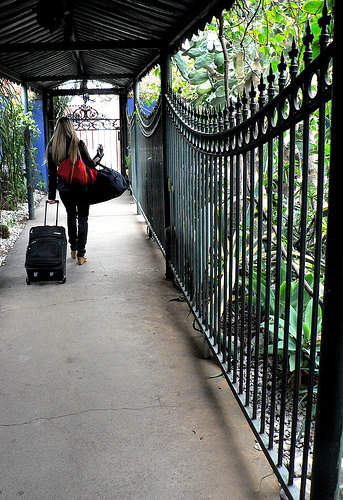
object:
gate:
[48, 115, 122, 172]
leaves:
[256, 43, 262, 55]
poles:
[266, 132, 285, 454]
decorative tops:
[313, 0, 334, 53]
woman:
[41, 114, 104, 266]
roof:
[0, 0, 238, 92]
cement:
[0, 193, 291, 500]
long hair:
[41, 114, 83, 168]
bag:
[56, 156, 98, 186]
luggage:
[24, 199, 68, 287]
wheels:
[25, 275, 31, 285]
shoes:
[77, 254, 88, 265]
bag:
[85, 161, 134, 206]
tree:
[269, 0, 282, 48]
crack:
[0, 404, 179, 430]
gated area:
[1, 0, 343, 500]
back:
[58, 138, 89, 200]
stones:
[2, 243, 5, 249]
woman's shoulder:
[77, 139, 87, 152]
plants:
[0, 100, 8, 202]